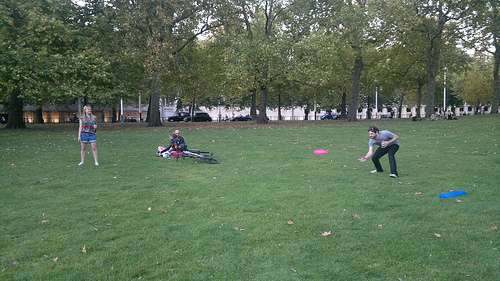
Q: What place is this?
A: It is a field.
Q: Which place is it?
A: It is a field.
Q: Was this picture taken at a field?
A: Yes, it was taken in a field.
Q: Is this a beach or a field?
A: It is a field.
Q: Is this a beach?
A: No, it is a field.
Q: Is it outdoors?
A: Yes, it is outdoors.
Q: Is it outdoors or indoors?
A: It is outdoors.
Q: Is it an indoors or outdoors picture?
A: It is outdoors.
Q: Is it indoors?
A: No, it is outdoors.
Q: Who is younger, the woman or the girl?
A: The girl is younger than the woman.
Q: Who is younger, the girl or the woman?
A: The girl is younger than the woman.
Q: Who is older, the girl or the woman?
A: The woman is older than the girl.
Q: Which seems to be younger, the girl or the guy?
A: The girl is younger than the guy.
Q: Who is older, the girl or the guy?
A: The guy is older than the girl.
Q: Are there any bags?
A: No, there are no bags.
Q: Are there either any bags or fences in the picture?
A: No, there are no bags or fences.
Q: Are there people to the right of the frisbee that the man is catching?
A: Yes, there is a person to the right of the frisbee.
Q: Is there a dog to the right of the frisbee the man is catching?
A: No, there is a person to the right of the frisbee.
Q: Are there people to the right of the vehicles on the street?
A: Yes, there is a person to the right of the vehicles.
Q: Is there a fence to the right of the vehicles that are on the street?
A: No, there is a person to the right of the vehicles.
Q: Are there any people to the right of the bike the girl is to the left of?
A: Yes, there is a person to the right of the bike.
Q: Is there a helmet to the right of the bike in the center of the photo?
A: No, there is a person to the right of the bike.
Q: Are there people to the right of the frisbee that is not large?
A: Yes, there is a person to the right of the frisbee.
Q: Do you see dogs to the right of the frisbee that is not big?
A: No, there is a person to the right of the frisbee.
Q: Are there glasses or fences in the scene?
A: No, there are no fences or glasses.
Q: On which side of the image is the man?
A: The man is on the right of the image.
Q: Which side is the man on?
A: The man is on the right of the image.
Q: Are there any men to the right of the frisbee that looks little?
A: Yes, there is a man to the right of the frisbee.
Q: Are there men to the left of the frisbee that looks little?
A: No, the man is to the right of the frisbee.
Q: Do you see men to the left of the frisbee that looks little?
A: No, the man is to the right of the frisbee.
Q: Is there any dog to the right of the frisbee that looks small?
A: No, there is a man to the right of the frisbee.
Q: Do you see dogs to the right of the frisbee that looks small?
A: No, there is a man to the right of the frisbee.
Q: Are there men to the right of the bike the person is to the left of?
A: Yes, there is a man to the right of the bike.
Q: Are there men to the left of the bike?
A: No, the man is to the right of the bike.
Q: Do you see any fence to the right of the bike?
A: No, there is a man to the right of the bike.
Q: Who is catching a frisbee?
A: The man is catching a frisbee.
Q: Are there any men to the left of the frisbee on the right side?
A: Yes, there is a man to the left of the frisbee.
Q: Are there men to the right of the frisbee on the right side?
A: No, the man is to the left of the frisbee.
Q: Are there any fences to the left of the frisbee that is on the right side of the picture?
A: No, there is a man to the left of the frisbee.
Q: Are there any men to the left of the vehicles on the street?
A: No, the man is to the right of the vehicles.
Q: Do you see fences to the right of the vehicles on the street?
A: No, there is a man to the right of the vehicles.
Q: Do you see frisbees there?
A: Yes, there is a frisbee.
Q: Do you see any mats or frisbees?
A: Yes, there is a frisbee.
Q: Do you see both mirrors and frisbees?
A: No, there is a frisbee but no mirrors.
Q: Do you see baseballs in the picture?
A: No, there are no baseballs.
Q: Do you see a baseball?
A: No, there are no baseballs.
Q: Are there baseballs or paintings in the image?
A: No, there are no baseballs or paintings.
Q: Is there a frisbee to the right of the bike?
A: Yes, there is a frisbee to the right of the bike.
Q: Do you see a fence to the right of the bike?
A: No, there is a frisbee to the right of the bike.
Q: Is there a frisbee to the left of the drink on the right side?
A: Yes, there is a frisbee to the left of the drink.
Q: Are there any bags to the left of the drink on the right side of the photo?
A: No, there is a frisbee to the left of the drink.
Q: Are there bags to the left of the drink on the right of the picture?
A: No, there is a frisbee to the left of the drink.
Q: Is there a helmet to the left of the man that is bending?
A: No, there is a frisbee to the left of the man.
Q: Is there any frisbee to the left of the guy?
A: Yes, there is a frisbee to the left of the guy.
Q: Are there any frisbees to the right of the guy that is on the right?
A: No, the frisbee is to the left of the guy.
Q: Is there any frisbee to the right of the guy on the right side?
A: No, the frisbee is to the left of the guy.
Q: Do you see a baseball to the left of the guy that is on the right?
A: No, there is a frisbee to the left of the guy.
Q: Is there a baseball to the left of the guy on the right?
A: No, there is a frisbee to the left of the guy.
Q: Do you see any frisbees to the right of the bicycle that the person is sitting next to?
A: Yes, there is a frisbee to the right of the bicycle.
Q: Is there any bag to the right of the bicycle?
A: No, there is a frisbee to the right of the bicycle.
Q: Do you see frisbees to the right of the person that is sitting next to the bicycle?
A: Yes, there is a frisbee to the right of the person.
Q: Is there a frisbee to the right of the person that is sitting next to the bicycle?
A: Yes, there is a frisbee to the right of the person.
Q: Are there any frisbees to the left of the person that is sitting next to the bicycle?
A: No, the frisbee is to the right of the person.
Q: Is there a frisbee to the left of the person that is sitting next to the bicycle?
A: No, the frisbee is to the right of the person.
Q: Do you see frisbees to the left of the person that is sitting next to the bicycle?
A: No, the frisbee is to the right of the person.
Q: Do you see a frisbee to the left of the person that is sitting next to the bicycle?
A: No, the frisbee is to the right of the person.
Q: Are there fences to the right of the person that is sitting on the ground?
A: No, there is a frisbee to the right of the person.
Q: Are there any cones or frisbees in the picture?
A: Yes, there is a frisbee.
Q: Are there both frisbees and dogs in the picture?
A: No, there is a frisbee but no dogs.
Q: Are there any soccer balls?
A: No, there are no soccer balls.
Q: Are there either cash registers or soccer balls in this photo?
A: No, there are no soccer balls or cash registers.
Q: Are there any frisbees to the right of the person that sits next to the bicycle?
A: Yes, there is a frisbee to the right of the person.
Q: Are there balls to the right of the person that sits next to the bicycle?
A: No, there is a frisbee to the right of the person.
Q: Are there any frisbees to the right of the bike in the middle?
A: Yes, there is a frisbee to the right of the bike.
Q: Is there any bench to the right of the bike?
A: No, there is a frisbee to the right of the bike.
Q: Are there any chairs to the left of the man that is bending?
A: No, there is a frisbee to the left of the man.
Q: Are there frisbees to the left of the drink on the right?
A: Yes, there is a frisbee to the left of the drink.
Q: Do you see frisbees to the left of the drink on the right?
A: Yes, there is a frisbee to the left of the drink.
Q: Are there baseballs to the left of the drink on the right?
A: No, there is a frisbee to the left of the drink.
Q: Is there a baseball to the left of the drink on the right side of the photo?
A: No, there is a frisbee to the left of the drink.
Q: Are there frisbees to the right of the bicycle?
A: Yes, there is a frisbee to the right of the bicycle.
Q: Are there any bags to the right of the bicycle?
A: No, there is a frisbee to the right of the bicycle.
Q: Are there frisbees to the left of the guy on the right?
A: Yes, there is a frisbee to the left of the guy.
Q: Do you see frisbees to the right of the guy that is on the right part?
A: No, the frisbee is to the left of the guy.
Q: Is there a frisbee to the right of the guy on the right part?
A: No, the frisbee is to the left of the guy.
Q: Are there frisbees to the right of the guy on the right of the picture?
A: No, the frisbee is to the left of the guy.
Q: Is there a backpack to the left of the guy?
A: No, there is a frisbee to the left of the guy.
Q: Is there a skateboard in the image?
A: No, there are no skateboards.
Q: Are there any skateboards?
A: No, there are no skateboards.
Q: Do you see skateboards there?
A: No, there are no skateboards.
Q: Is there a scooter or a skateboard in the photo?
A: No, there are no skateboards or scooters.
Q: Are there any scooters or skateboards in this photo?
A: No, there are no skateboards or scooters.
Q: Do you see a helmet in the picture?
A: No, there are no helmets.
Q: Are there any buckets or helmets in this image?
A: No, there are no helmets or buckets.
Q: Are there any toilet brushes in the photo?
A: No, there are no toilet brushes.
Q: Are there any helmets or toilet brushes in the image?
A: No, there are no toilet brushes or helmets.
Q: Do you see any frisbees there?
A: Yes, there is a frisbee.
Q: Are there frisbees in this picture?
A: Yes, there is a frisbee.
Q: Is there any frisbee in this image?
A: Yes, there is a frisbee.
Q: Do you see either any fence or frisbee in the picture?
A: Yes, there is a frisbee.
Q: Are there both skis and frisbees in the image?
A: No, there is a frisbee but no skis.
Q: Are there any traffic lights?
A: No, there are no traffic lights.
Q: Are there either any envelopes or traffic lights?
A: No, there are no traffic lights or envelopes.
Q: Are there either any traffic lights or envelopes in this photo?
A: No, there are no traffic lights or envelopes.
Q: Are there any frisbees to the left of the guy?
A: Yes, there is a frisbee to the left of the guy.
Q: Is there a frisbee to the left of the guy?
A: Yes, there is a frisbee to the left of the guy.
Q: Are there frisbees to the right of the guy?
A: No, the frisbee is to the left of the guy.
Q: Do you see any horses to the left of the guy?
A: No, there is a frisbee to the left of the guy.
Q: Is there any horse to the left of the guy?
A: No, there is a frisbee to the left of the guy.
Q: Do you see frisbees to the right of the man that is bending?
A: No, the frisbee is to the left of the man.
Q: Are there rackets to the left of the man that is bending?
A: No, there is a frisbee to the left of the man.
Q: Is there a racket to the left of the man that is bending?
A: No, there is a frisbee to the left of the man.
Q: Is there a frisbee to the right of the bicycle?
A: Yes, there is a frisbee to the right of the bicycle.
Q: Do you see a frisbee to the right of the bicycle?
A: Yes, there is a frisbee to the right of the bicycle.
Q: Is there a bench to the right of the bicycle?
A: No, there is a frisbee to the right of the bicycle.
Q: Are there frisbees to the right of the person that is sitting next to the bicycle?
A: Yes, there is a frisbee to the right of the person.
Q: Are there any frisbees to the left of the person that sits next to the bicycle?
A: No, the frisbee is to the right of the person.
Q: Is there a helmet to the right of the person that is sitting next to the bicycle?
A: No, there is a frisbee to the right of the person.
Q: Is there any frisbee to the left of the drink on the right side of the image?
A: Yes, there is a frisbee to the left of the drink.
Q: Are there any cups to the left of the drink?
A: No, there is a frisbee to the left of the drink.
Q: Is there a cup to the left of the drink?
A: No, there is a frisbee to the left of the drink.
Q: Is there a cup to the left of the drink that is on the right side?
A: No, there is a frisbee to the left of the drink.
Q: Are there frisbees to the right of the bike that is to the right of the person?
A: Yes, there is a frisbee to the right of the bike.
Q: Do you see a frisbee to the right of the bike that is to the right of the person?
A: Yes, there is a frisbee to the right of the bike.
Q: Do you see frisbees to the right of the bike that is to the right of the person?
A: Yes, there is a frisbee to the right of the bike.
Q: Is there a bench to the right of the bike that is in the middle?
A: No, there is a frisbee to the right of the bike.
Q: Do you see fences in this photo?
A: No, there are no fences.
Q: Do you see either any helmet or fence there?
A: No, there are no fences or helmets.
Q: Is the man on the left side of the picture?
A: No, the man is on the right of the image.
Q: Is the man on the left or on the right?
A: The man is on the right of the image.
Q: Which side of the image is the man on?
A: The man is on the right of the image.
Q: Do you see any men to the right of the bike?
A: Yes, there is a man to the right of the bike.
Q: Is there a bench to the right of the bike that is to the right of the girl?
A: No, there is a man to the right of the bike.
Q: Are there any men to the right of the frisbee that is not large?
A: Yes, there is a man to the right of the frisbee.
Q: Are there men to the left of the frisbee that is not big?
A: No, the man is to the right of the frisbee.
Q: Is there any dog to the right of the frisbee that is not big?
A: No, there is a man to the right of the frisbee.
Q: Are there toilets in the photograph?
A: No, there are no toilets.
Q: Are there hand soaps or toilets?
A: No, there are no toilets or hand soaps.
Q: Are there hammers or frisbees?
A: Yes, there is a frisbee.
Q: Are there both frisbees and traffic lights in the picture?
A: No, there is a frisbee but no traffic lights.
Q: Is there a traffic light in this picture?
A: No, there are no traffic lights.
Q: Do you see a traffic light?
A: No, there are no traffic lights.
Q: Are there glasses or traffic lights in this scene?
A: No, there are no traffic lights or glasses.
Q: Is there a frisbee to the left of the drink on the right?
A: Yes, there is a frisbee to the left of the drink.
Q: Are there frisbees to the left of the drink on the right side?
A: Yes, there is a frisbee to the left of the drink.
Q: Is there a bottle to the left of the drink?
A: No, there is a frisbee to the left of the drink.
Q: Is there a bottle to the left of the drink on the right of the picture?
A: No, there is a frisbee to the left of the drink.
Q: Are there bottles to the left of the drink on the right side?
A: No, there is a frisbee to the left of the drink.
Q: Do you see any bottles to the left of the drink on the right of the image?
A: No, there is a frisbee to the left of the drink.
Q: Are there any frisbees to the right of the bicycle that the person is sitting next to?
A: Yes, there is a frisbee to the right of the bicycle.